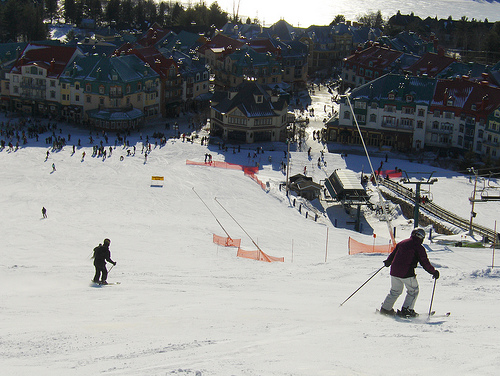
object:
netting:
[210, 233, 243, 249]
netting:
[235, 247, 286, 264]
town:
[0, 0, 499, 178]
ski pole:
[426, 277, 437, 319]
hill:
[0, 244, 499, 376]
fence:
[346, 236, 394, 255]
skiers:
[50, 162, 57, 169]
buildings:
[324, 72, 499, 161]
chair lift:
[413, 187, 433, 203]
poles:
[335, 264, 385, 308]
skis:
[374, 306, 438, 317]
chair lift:
[478, 174, 500, 202]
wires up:
[343, 94, 397, 248]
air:
[3, 221, 67, 247]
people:
[80, 149, 85, 163]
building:
[210, 79, 291, 145]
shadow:
[0, 106, 211, 151]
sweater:
[381, 236, 438, 278]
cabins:
[57, 53, 161, 125]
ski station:
[324, 168, 370, 207]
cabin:
[341, 44, 402, 92]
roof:
[346, 74, 437, 109]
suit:
[92, 244, 114, 280]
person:
[379, 226, 440, 319]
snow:
[0, 83, 499, 374]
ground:
[0, 118, 499, 375]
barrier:
[212, 233, 244, 249]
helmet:
[411, 226, 427, 239]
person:
[91, 238, 117, 287]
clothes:
[91, 243, 116, 282]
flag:
[149, 174, 163, 181]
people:
[73, 144, 76, 154]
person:
[42, 206, 48, 219]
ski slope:
[1, 247, 500, 373]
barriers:
[234, 246, 286, 262]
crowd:
[1, 129, 169, 171]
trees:
[0, 2, 225, 43]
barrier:
[184, 158, 241, 171]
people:
[208, 154, 212, 159]